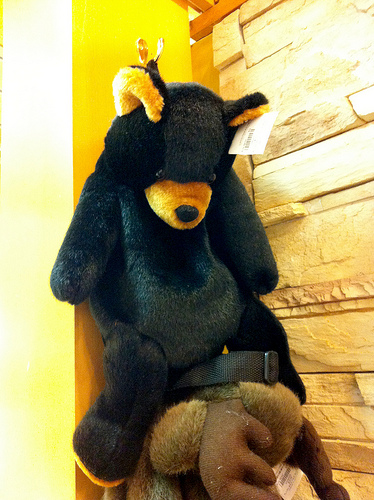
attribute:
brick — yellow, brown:
[326, 300, 360, 396]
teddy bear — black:
[49, 66, 306, 485]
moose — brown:
[118, 382, 350, 497]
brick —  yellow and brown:
[303, 127, 353, 196]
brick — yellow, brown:
[256, 215, 339, 269]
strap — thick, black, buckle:
[167, 339, 292, 387]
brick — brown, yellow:
[277, 191, 352, 332]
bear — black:
[49, 56, 308, 487]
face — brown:
[128, 122, 232, 230]